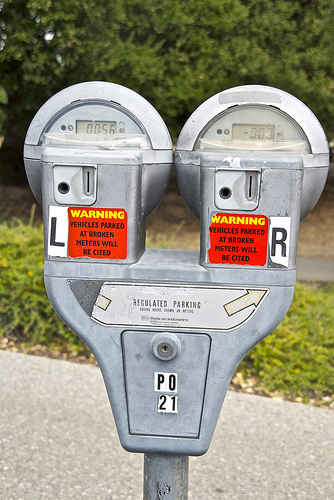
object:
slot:
[86, 170, 91, 193]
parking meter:
[21, 81, 174, 265]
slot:
[248, 176, 253, 197]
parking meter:
[174, 84, 330, 268]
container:
[41, 250, 296, 455]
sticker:
[66, 207, 128, 262]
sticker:
[206, 210, 268, 267]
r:
[272, 227, 285, 258]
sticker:
[267, 216, 291, 268]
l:
[50, 216, 65, 248]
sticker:
[45, 205, 70, 257]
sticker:
[154, 372, 177, 413]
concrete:
[0, 350, 334, 499]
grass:
[0, 224, 83, 349]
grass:
[239, 282, 334, 406]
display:
[76, 120, 118, 134]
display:
[230, 124, 275, 141]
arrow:
[223, 290, 268, 317]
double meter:
[24, 81, 330, 456]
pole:
[142, 451, 190, 498]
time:
[100, 124, 114, 135]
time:
[265, 127, 274, 139]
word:
[69, 209, 127, 221]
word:
[212, 214, 267, 228]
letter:
[156, 373, 165, 391]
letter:
[168, 374, 177, 392]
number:
[158, 394, 168, 412]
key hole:
[156, 341, 173, 359]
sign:
[89, 283, 271, 334]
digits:
[244, 125, 273, 142]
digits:
[86, 122, 116, 134]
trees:
[0, 2, 81, 156]